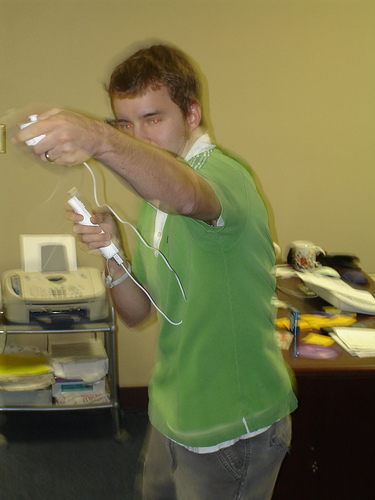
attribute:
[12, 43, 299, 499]
male — playing, white, young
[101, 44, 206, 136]
hair — brown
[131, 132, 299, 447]
shirt — green, short sleeved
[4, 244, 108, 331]
fax machine — old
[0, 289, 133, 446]
cart — metal, silver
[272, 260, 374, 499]
desk — cluttered, brown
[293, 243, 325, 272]
coffee mug — small, white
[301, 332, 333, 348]
post it note — yellow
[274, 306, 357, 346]
post it notes — yellow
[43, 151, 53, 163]
wedding band — gold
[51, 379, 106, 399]
rea of paper — unopened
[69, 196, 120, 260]
wiimote — white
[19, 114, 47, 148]
nanchuck — white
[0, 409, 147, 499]
floor — dark blue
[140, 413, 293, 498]
pants — grey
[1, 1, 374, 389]
wall — beige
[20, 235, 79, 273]
paper — white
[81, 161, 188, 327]
chord — white